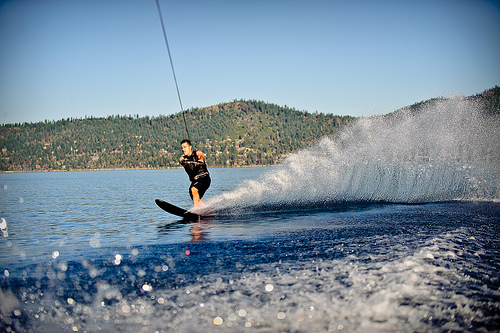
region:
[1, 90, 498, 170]
green trees on the hills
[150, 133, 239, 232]
a man skiing in the water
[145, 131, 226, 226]
a man skiing in the lake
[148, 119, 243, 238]
a man cable skiing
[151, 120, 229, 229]
a man cable skiing in the lake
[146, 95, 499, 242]
a man making waves from skiing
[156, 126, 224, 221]
man wearing a life jacket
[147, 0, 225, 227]
a man holding on to a cable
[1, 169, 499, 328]
a lake with blue water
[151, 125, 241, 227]
a man skiing on blue water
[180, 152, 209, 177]
black padded life jacket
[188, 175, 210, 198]
black cotton swim shorts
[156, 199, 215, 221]
black water ski in water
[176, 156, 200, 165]
water ski handle in hands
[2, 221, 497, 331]
water splashing from boat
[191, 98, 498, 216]
water splashing from water ski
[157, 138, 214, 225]
man standing on water ski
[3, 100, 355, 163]
green trees on hills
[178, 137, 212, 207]
man wearing life vest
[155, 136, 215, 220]
man water skiing in lake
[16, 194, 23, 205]
clear dot of water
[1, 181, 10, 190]
clear dot of water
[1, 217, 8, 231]
clear dot of water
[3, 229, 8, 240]
clear dot of water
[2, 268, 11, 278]
clear dot of water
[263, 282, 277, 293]
clear dot of water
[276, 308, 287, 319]
clear dot of water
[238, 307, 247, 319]
clear dot of water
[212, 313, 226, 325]
clear dot of water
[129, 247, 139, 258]
clear dot of water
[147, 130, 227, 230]
a surfer in the ocean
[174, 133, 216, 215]
surfer wears black clothes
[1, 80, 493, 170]
a mountain on the background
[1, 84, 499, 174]
mountain is covered with trees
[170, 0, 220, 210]
man holding a handle with a rope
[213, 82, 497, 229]
a big splash above the water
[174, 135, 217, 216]
surfer wears black shorts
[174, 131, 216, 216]
surfer wears a black tank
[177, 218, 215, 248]
reflection of a person on the water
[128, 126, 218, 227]
man on wakeboard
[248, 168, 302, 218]
white splashes in blue water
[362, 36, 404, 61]
white clouds in blue sky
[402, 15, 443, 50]
white clouds in blue sky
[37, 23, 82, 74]
white clouds in blue sky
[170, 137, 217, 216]
man on wakeboard parasailing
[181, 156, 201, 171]
man holding rope handle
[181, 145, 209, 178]
man wearing life vest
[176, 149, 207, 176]
man's vest is black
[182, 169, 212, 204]
man's shorts are black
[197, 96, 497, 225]
wake from parasailer behind man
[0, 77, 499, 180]
small hill behind water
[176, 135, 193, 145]
man has short hair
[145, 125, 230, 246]
man wakeboarding on water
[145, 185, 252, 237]
black wakeboard under man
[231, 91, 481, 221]
white water spray from man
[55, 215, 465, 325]
white water spray from boat